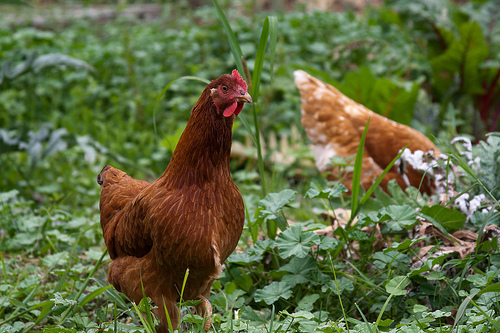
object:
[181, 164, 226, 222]
feathers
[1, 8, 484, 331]
grass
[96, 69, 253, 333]
hen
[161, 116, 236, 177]
neck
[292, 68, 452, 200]
hen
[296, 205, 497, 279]
dead leaves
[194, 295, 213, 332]
claw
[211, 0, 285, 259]
tall weed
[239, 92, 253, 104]
beak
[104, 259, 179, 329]
leg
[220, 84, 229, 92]
eye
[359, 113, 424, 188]
wing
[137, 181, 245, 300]
breast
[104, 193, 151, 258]
wing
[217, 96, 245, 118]
red skin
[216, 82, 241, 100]
red cheek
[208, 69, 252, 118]
head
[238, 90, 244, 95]
holes in beak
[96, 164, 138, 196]
back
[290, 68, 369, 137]
back